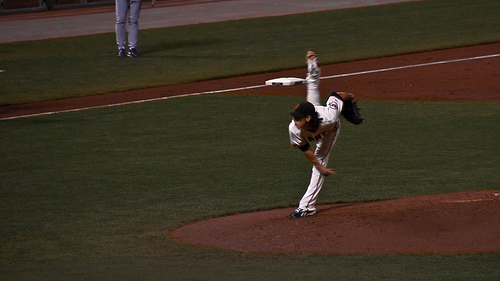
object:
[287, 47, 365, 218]
baseball player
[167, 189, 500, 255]
mound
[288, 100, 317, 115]
hat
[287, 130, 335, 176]
arm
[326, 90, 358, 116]
arm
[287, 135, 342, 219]
leg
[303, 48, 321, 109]
leg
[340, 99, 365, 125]
glove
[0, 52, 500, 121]
line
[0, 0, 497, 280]
field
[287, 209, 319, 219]
shoe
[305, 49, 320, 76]
shoe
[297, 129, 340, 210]
trousers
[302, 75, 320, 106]
trousers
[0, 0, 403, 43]
edge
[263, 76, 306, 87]
base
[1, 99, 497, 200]
grass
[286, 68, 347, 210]
uniform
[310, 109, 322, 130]
hair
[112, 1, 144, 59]
person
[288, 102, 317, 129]
head